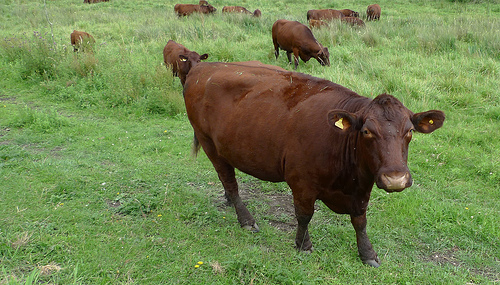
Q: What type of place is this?
A: It is a field.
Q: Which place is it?
A: It is a field.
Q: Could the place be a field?
A: Yes, it is a field.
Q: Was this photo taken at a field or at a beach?
A: It was taken at a field.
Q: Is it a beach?
A: No, it is a field.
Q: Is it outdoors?
A: Yes, it is outdoors.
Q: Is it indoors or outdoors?
A: It is outdoors.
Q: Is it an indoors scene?
A: No, it is outdoors.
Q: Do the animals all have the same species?
A: Yes, all the animals are cows.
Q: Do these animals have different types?
A: No, all the animals are cows.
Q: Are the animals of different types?
A: No, all the animals are cows.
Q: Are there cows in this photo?
A: Yes, there is a cow.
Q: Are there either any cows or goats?
A: Yes, there is a cow.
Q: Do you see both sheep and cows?
A: No, there is a cow but no sheep.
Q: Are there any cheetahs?
A: No, there are no cheetahs.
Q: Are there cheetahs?
A: No, there are no cheetahs.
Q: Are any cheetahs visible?
A: No, there are no cheetahs.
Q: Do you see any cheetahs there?
A: No, there are no cheetahs.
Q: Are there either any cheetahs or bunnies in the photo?
A: No, there are no cheetahs or bunnies.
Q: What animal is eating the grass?
A: The cow is eating the grass.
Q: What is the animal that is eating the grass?
A: The animal is a cow.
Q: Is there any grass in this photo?
A: Yes, there is grass.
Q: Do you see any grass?
A: Yes, there is grass.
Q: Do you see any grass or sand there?
A: Yes, there is grass.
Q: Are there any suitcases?
A: No, there are no suitcases.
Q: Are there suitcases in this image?
A: No, there are no suitcases.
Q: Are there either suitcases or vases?
A: No, there are no suitcases or vases.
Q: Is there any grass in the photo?
A: Yes, there is grass.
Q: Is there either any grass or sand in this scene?
A: Yes, there is grass.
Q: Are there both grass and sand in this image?
A: No, there is grass but no sand.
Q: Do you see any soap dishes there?
A: No, there are no soap dishes.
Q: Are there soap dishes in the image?
A: No, there are no soap dishes.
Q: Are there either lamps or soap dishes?
A: No, there are no soap dishes or lamps.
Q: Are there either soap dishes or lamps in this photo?
A: No, there are no soap dishes or lamps.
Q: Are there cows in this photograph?
A: Yes, there is a cow.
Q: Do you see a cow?
A: Yes, there is a cow.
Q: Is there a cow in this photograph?
A: Yes, there is a cow.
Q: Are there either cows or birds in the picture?
A: Yes, there is a cow.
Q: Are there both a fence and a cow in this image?
A: No, there is a cow but no fences.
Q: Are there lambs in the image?
A: No, there are no lambs.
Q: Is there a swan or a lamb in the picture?
A: No, there are no lambs or swans.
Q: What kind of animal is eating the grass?
A: The animal is a cow.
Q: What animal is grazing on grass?
A: The cow is grazing on grass.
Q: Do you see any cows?
A: Yes, there is a cow.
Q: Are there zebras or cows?
A: Yes, there is a cow.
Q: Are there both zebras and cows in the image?
A: No, there is a cow but no zebras.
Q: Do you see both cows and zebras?
A: No, there is a cow but no zebras.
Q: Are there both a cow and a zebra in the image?
A: No, there is a cow but no zebras.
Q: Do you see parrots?
A: No, there are no parrots.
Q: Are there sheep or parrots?
A: No, there are no parrots or sheep.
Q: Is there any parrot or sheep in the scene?
A: No, there are no parrots or sheep.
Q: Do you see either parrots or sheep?
A: No, there are no parrots or sheep.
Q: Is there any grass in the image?
A: Yes, there is grass.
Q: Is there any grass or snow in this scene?
A: Yes, there is grass.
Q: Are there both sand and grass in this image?
A: No, there is grass but no sand.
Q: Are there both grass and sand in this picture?
A: No, there is grass but no sand.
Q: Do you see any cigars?
A: No, there are no cigars.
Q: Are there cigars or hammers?
A: No, there are no cigars or hammers.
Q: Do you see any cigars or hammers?
A: No, there are no cigars or hammers.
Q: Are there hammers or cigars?
A: No, there are no cigars or hammers.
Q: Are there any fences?
A: No, there are no fences.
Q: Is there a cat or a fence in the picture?
A: No, there are no fences or cats.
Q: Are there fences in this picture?
A: No, there are no fences.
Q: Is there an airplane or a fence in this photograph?
A: No, there are no fences or airplanes.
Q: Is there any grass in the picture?
A: Yes, there is grass.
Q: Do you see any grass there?
A: Yes, there is grass.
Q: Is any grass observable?
A: Yes, there is grass.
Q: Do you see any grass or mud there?
A: Yes, there is grass.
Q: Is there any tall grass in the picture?
A: Yes, there is tall grass.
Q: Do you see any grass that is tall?
A: Yes, there is grass that is tall.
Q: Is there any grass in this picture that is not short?
A: Yes, there is tall grass.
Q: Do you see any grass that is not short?
A: Yes, there is tall grass.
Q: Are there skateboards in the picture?
A: No, there are no skateboards.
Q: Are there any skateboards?
A: No, there are no skateboards.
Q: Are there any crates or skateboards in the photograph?
A: No, there are no skateboards or crates.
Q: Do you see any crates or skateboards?
A: No, there are no skateboards or crates.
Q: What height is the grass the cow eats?
A: The grass is tall.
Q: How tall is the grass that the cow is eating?
A: The grass is tall.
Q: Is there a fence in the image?
A: No, there are no fences.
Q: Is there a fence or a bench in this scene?
A: No, there are no fences or benches.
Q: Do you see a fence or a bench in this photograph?
A: No, there are no fences or benches.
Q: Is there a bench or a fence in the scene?
A: No, there are no fences or benches.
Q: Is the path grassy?
A: Yes, the path is grassy.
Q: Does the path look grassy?
A: Yes, the path is grassy.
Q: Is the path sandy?
A: No, the path is grassy.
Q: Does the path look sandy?
A: No, the path is grassy.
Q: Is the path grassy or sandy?
A: The path is grassy.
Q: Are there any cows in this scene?
A: Yes, there is a cow.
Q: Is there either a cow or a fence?
A: Yes, there is a cow.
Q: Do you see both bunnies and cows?
A: No, there is a cow but no bunnies.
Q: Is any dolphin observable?
A: No, there are no dolphins.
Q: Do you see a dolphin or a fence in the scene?
A: No, there are no dolphins or fences.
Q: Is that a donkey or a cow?
A: That is a cow.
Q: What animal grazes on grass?
A: The cow grazes on grass.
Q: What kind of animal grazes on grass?
A: The animal is a cow.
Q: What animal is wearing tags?
A: The cow is wearing tags.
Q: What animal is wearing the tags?
A: The cow is wearing tags.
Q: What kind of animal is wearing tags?
A: The animal is a cow.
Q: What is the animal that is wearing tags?
A: The animal is a cow.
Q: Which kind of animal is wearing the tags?
A: The animal is a cow.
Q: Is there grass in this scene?
A: Yes, there is grass.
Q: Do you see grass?
A: Yes, there is grass.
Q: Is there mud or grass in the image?
A: Yes, there is grass.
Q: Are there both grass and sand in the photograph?
A: No, there is grass but no sand.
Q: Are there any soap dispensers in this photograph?
A: No, there are no soap dispensers.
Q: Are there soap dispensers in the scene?
A: No, there are no soap dispensers.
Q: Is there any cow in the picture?
A: Yes, there is a cow.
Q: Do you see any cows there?
A: Yes, there is a cow.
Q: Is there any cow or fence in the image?
A: Yes, there is a cow.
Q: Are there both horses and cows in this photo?
A: No, there is a cow but no horses.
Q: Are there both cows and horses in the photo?
A: No, there is a cow but no horses.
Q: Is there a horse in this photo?
A: No, there are no horses.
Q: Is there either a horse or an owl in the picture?
A: No, there are no horses or owls.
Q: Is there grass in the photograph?
A: Yes, there is grass.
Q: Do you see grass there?
A: Yes, there is grass.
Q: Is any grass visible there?
A: Yes, there is grass.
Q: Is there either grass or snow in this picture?
A: Yes, there is grass.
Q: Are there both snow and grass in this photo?
A: No, there is grass but no snow.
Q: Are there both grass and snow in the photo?
A: No, there is grass but no snow.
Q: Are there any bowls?
A: No, there are no bowls.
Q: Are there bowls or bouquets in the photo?
A: No, there are no bowls or bouquets.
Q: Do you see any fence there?
A: No, there are no fences.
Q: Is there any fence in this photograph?
A: No, there are no fences.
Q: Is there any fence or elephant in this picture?
A: No, there are no fences or elephants.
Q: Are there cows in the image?
A: Yes, there is a cow.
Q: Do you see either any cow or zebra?
A: Yes, there is a cow.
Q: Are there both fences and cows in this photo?
A: No, there is a cow but no fences.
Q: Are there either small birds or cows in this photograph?
A: Yes, there is a small cow.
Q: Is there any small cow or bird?
A: Yes, there is a small cow.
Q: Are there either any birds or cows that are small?
A: Yes, the cow is small.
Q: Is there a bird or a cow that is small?
A: Yes, the cow is small.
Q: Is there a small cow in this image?
A: Yes, there is a small cow.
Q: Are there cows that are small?
A: Yes, there is a cow that is small.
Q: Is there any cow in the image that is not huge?
A: Yes, there is a small cow.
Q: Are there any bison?
A: No, there are no bison.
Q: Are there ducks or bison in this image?
A: No, there are no bison or ducks.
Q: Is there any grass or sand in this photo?
A: Yes, there is grass.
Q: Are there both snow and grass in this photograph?
A: No, there is grass but no snow.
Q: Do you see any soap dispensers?
A: No, there are no soap dispensers.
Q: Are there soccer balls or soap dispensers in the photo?
A: No, there are no soap dispensers or soccer balls.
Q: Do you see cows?
A: Yes, there is a cow.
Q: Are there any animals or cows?
A: Yes, there is a cow.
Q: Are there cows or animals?
A: Yes, there is a cow.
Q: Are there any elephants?
A: No, there are no elephants.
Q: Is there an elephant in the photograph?
A: No, there are no elephants.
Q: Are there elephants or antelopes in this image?
A: No, there are no elephants or antelopes.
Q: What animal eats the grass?
A: The cow eats the grass.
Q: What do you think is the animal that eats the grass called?
A: The animal is a cow.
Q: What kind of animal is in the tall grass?
A: The animal is a cow.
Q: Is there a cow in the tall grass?
A: Yes, there is a cow in the grass.